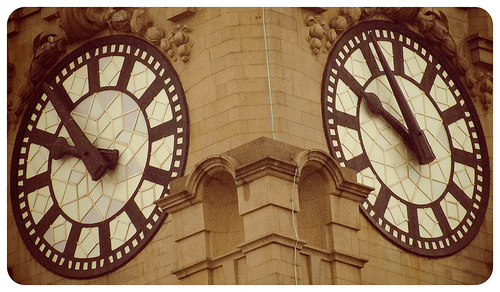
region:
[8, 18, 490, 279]
two clocks on the sides of the tower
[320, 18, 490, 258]
a brown and white tower-clock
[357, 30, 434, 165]
brown hour and minute hands on the clock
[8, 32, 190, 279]
9:54 on a tower clock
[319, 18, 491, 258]
9:56 on a tower clock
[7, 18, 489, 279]
two tower clocks with different times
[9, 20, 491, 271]
clocks on two sides of the tower building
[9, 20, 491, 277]
a brick clock tower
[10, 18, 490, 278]
a historical clock tower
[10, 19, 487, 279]
two clocks on a wall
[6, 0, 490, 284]
a clock tower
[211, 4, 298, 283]
corner of a tower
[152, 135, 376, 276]
edges of a corner on a tower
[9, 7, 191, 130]
decorations around a clock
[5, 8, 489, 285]
a structure made from bricks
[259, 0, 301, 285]
a power or phone line running down the tower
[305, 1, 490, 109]
decorations for the right side clock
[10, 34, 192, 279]
a clock that says 8:50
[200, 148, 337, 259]
a hollowed out part of the corner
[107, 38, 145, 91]
BLack line on a white clock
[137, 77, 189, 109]
BLack line on a white clock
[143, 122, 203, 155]
BLack line on a white clock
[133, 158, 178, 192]
BLack line on a white clock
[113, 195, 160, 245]
BLack line on a white clock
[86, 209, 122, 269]
BLack line on a white clock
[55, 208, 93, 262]
BLack line on a white clock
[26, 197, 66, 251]
BLack line on a white clock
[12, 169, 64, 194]
BLack line on a white clock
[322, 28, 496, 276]
A black and white tower clock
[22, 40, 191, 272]
A black and white tower clock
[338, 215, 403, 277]
A brown house wall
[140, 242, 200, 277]
A brown house wall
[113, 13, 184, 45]
A brown house wall's decorations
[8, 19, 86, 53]
A brown house wall's decorations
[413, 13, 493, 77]
A brown house wall's decorations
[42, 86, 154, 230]
A clock on the wall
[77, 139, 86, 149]
The minute hand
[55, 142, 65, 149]
The hour hand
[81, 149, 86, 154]
Pin holding the clock hands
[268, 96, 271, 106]
A cable on the wall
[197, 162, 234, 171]
An arch on the wall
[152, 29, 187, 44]
Decorations next to the clock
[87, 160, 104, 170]
The lower end of the minute hand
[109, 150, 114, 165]
The lower end of the hour hand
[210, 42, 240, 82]
Bricks on the wall